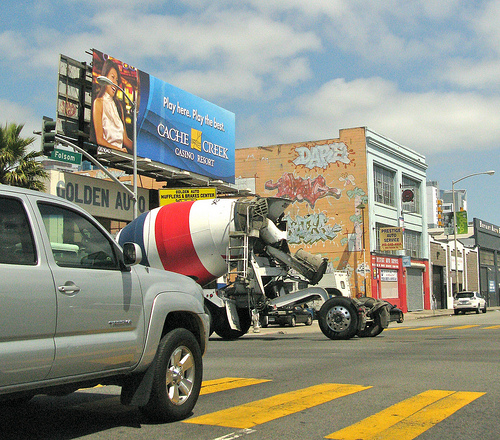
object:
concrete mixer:
[113, 193, 405, 339]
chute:
[262, 240, 328, 284]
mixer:
[113, 202, 291, 277]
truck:
[1, 182, 212, 418]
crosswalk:
[180, 364, 497, 439]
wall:
[234, 147, 372, 300]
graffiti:
[272, 148, 357, 243]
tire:
[158, 329, 202, 416]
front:
[138, 268, 207, 353]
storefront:
[370, 252, 431, 315]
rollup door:
[406, 265, 425, 310]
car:
[452, 290, 489, 314]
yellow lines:
[200, 375, 486, 439]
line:
[212, 425, 250, 439]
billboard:
[91, 47, 237, 186]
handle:
[58, 278, 80, 296]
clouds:
[296, 76, 499, 153]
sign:
[444, 208, 471, 236]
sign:
[56, 172, 150, 222]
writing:
[57, 181, 150, 215]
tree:
[0, 122, 49, 188]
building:
[235, 127, 437, 314]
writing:
[153, 94, 230, 170]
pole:
[129, 83, 144, 254]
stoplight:
[39, 113, 58, 159]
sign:
[48, 147, 83, 164]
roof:
[241, 127, 427, 165]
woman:
[94, 61, 134, 152]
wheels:
[315, 294, 362, 341]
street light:
[450, 170, 494, 318]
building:
[35, 157, 153, 226]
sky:
[4, 0, 495, 81]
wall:
[370, 196, 431, 309]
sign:
[378, 222, 405, 249]